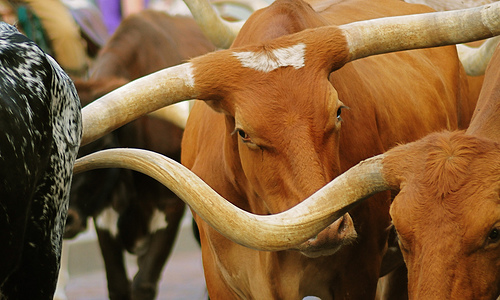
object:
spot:
[234, 43, 305, 72]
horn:
[73, 147, 389, 252]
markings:
[1, 23, 82, 300]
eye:
[236, 127, 250, 139]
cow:
[57, 9, 215, 299]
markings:
[94, 205, 122, 236]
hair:
[422, 128, 481, 195]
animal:
[1, 21, 85, 299]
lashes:
[230, 128, 239, 136]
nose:
[303, 214, 354, 248]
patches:
[149, 202, 169, 233]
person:
[0, 0, 91, 79]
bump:
[233, 0, 326, 46]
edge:
[80, 63, 189, 107]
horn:
[82, 64, 195, 145]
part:
[98, 203, 189, 298]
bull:
[71, 42, 499, 300]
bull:
[80, 0, 499, 300]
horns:
[340, 1, 500, 61]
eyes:
[334, 106, 343, 120]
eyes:
[485, 224, 499, 246]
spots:
[0, 22, 84, 299]